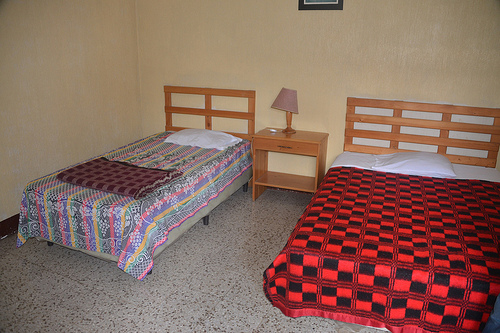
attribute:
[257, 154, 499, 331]
comforter — red , black 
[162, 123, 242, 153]
pillow — white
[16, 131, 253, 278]
blanket — colorful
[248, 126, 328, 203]
stand — wooden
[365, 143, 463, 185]
pillow — white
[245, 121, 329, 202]
nightstand — brown 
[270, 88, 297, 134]
lamp — small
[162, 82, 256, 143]
headboard — brown 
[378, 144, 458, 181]
pillow — white, small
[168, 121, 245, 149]
pillow — white, small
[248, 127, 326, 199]
night stand — wooden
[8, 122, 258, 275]
sheet — white 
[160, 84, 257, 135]
headboard — brown 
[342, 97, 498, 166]
frame — wooden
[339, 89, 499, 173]
headboard — wooden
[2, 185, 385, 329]
floor — white 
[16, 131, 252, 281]
bedspread — patterned, floral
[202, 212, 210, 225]
leg — black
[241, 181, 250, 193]
leg — black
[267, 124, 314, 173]
table — wooden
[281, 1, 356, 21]
frame — black